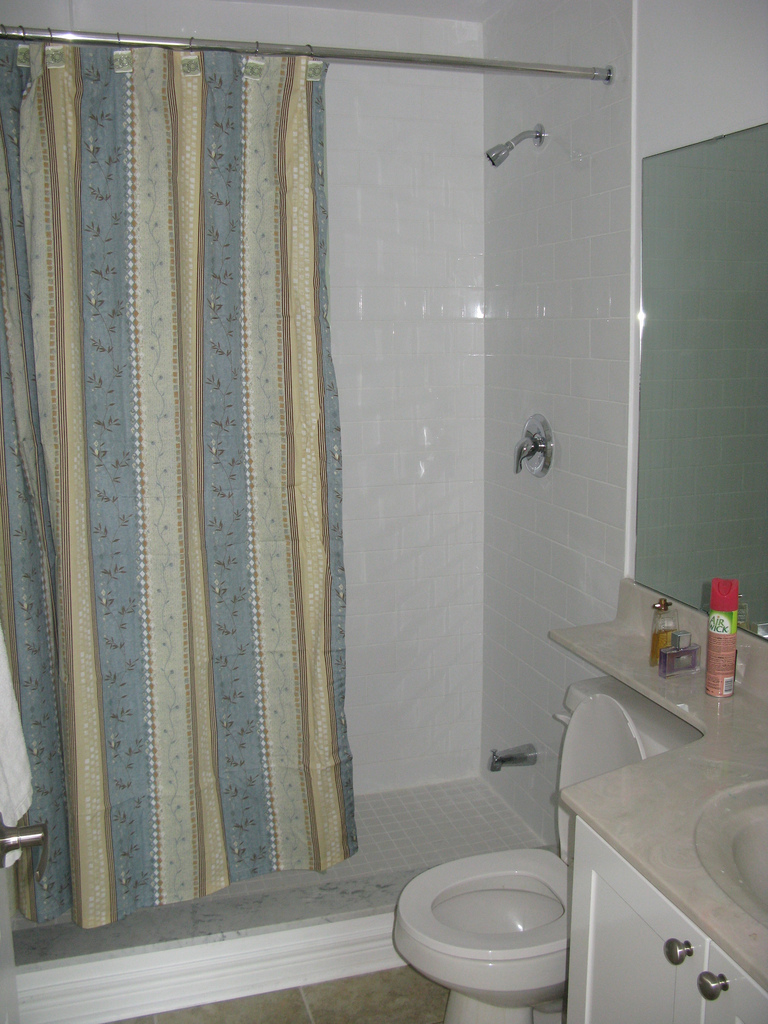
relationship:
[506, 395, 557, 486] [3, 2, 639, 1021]
faucet mounted inside shower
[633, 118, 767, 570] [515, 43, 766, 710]
mirror on wall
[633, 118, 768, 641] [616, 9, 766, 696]
mirror on wall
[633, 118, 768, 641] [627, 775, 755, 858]
mirror above marble counter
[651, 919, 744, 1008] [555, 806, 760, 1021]
knobs on doors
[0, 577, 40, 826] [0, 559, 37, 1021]
towel hanging door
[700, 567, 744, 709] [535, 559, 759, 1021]
air freshener on counter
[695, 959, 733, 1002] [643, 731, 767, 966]
knobs on sink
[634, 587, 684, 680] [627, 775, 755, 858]
purfume on marble counter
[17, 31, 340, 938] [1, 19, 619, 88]
shower curtain hanging curtain rod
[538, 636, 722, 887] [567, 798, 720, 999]
marble counter over cabinets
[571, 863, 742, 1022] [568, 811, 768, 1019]
handles on cabinet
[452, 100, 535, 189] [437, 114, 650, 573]
shower head on wall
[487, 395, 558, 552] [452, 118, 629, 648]
faucet on wall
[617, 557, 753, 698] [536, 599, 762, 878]
bottles on marble counter